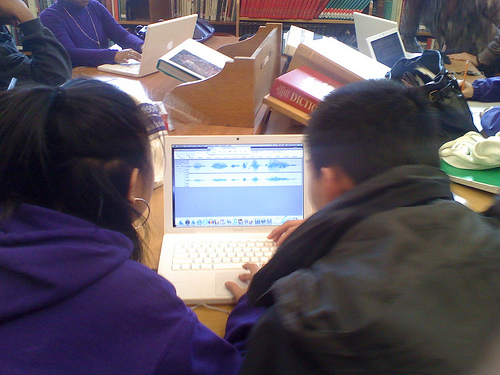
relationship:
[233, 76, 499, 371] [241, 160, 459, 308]
boy wearing scarf